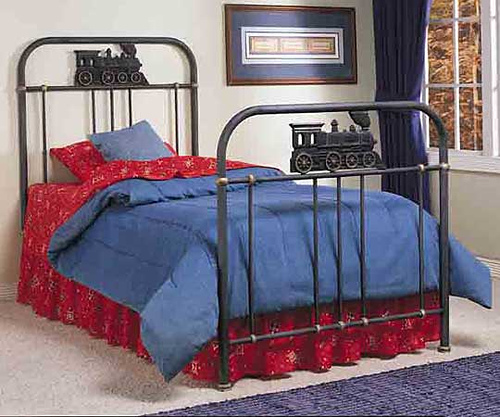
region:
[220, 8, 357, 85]
a wall hanging on the wall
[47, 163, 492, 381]
a blue comforter on the bed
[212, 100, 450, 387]
the foot board of the bed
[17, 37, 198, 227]
the headboard of the bed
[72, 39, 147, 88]
an engine on the headboard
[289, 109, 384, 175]
an engine on the foot board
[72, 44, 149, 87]
a locomotive on the headboard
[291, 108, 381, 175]
a locomotive on the foot board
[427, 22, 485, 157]
four panes of a window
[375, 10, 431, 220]
a curtain by the window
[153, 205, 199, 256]
A blue duvet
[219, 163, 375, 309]
Metal railings on the bed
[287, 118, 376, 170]
A train wagon statue on the bed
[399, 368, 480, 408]
A carpet on the floor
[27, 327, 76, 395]
A floor in the room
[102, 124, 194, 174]
A pillow on the bed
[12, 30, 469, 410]
The bed in the bedroom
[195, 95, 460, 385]
The foot of the bed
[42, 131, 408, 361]
The mattress of the bed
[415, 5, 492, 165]
The window is open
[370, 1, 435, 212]
The curtain is the color blue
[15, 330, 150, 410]
The floor has white carper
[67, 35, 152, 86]
The train on the bed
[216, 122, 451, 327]
The bed rails are the color black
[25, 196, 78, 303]
The bed sheet is the color red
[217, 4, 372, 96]
The picture hanging on the wall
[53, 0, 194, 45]
The wall is white and clean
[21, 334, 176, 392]
The floor is light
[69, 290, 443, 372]
The bed skirt is red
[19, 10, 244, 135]
The head board is metal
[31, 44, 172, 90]
A train is on the headboard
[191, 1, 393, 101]
The picture is on the wall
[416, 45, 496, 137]
Trees are outside the window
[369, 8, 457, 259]
The curtains are blue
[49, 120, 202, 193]
The pillows are piled up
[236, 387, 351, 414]
The rug is blue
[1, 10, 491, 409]
a bedroom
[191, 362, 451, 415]
a blue rug in front of the bed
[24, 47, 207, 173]
the headboard of the bed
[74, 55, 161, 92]
a train decoration on the headboard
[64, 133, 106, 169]
a red pillow on the bed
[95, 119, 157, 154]
a blue pillow on the bed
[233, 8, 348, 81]
a picture hanging on the wall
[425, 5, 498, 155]
a window in the room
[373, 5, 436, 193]
blue curtains on the window